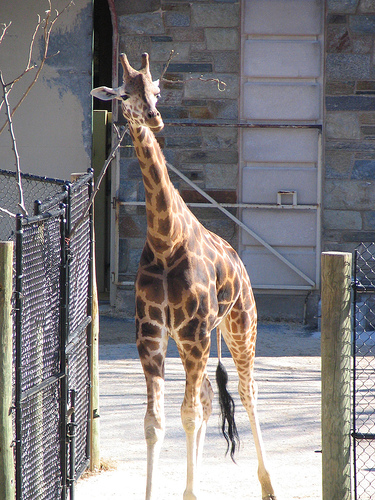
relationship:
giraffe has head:
[88, 46, 272, 499] [87, 45, 181, 136]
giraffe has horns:
[88, 46, 272, 499] [116, 48, 153, 71]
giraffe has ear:
[88, 46, 272, 499] [89, 81, 125, 107]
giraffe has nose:
[88, 46, 272, 499] [145, 109, 165, 121]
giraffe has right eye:
[88, 46, 272, 499] [120, 93, 132, 103]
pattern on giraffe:
[140, 254, 198, 307] [88, 46, 272, 499]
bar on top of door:
[66, 385, 80, 498] [13, 209, 88, 499]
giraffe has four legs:
[88, 46, 272, 499] [132, 317, 284, 499]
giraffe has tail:
[88, 46, 272, 499] [211, 330, 245, 462]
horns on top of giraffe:
[116, 48, 153, 71] [88, 46, 272, 499]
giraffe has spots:
[88, 46, 272, 499] [152, 164, 169, 212]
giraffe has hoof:
[88, 46, 272, 499] [258, 490, 278, 499]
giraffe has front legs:
[88, 46, 272, 499] [133, 314, 216, 499]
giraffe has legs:
[88, 46, 272, 499] [132, 317, 284, 499]